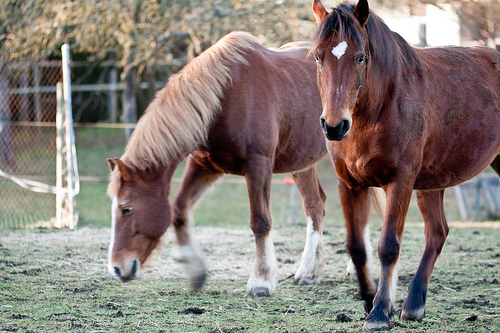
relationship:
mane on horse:
[115, 28, 272, 183] [54, 16, 357, 308]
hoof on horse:
[360, 313, 399, 331] [305, 2, 497, 330]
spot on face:
[327, 39, 356, 60] [307, 2, 373, 144]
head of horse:
[106, 157, 170, 283] [104, 28, 333, 301]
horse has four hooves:
[112, 94, 342, 296] [187, 224, 325, 333]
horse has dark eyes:
[384, 121, 493, 188] [351, 52, 370, 69]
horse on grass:
[104, 29, 389, 296] [96, 259, 466, 296]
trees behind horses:
[7, 51, 289, 53] [52, 101, 433, 333]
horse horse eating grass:
[104, 29, 389, 296] [0, 225, 500, 333]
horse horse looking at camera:
[304, 0, 500, 333] [271, 104, 340, 223]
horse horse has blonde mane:
[104, 29, 389, 296] [137, 99, 214, 167]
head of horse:
[93, 128, 188, 292] [234, 103, 294, 145]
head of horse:
[290, 52, 380, 157] [412, 146, 461, 178]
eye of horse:
[114, 201, 135, 226] [204, 121, 264, 194]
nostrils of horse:
[320, 104, 361, 164] [382, 125, 455, 194]